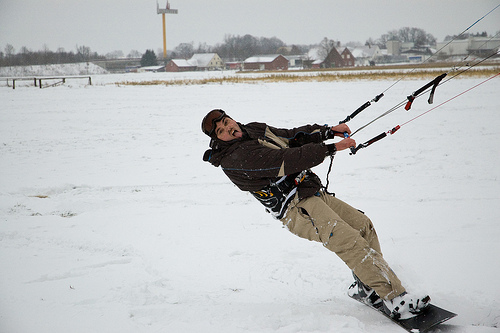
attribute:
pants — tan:
[276, 185, 407, 296]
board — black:
[349, 279, 457, 330]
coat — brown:
[202, 123, 333, 205]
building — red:
[245, 53, 288, 72]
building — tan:
[314, 45, 366, 69]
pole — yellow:
[161, 12, 168, 61]